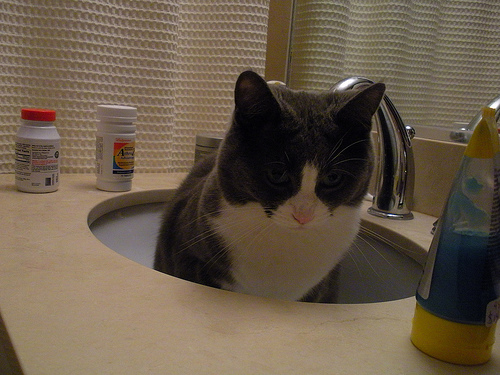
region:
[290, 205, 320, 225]
Nose of sitting cat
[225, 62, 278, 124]
Ear of sitting cat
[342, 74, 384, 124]
Ear of sitting cat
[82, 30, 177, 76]
Part of mini blinds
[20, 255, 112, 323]
Part of bathroom sink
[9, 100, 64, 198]
Supplement bottle on sink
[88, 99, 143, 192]
Supplement bottle on sink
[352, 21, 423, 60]
Part of mini blinds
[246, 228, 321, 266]
White chest of sitting cat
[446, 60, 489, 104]
Part of mini blinds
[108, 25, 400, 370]
a gray and white cat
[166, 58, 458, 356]
a gray and white cat in a sink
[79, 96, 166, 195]
a white pill bottle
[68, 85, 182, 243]
a white pill bottle on a sink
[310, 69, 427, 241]
a silver sink faucet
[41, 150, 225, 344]
a tan sink counter top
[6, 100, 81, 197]
a white bottle with red cap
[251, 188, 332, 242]
pink nose on a cat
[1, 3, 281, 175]
a white shower curtain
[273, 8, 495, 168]
a mirror on the wall in a bathroom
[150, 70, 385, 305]
Black and grey cat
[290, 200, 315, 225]
Pink nose on cat's face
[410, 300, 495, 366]
Yellow lid on container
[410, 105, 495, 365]
Yellow and blue tube on counter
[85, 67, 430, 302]
Cat sitting in bathroom sink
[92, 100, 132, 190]
White container sitting on counter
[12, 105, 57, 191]
White container with red lid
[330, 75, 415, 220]
Chrome faucet near bathroom sink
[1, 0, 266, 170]
White patterned wall in bathroom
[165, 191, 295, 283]
Whiskers on cat's face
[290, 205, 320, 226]
Nose of seated cat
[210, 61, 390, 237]
Head of seated cat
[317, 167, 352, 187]
Eye of seated cat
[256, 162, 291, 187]
Eye of seated cat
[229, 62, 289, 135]
Ear of seated cat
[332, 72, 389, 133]
Ear of seated cat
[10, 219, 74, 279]
Part of bathroom sink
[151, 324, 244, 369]
Part of bathroom sink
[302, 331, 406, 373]
Part of bathroom sink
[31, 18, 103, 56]
Part of white mini blinds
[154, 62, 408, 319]
a cat is in the sink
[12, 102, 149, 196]
some medicine is on the counter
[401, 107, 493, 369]
a bottle of lotion is on the counter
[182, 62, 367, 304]
the cat is grey and white in color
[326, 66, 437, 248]
the fixtures are silver in color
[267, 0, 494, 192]
a mirror is on the wall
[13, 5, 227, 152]
a white curtain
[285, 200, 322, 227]
the cats nose is pink in color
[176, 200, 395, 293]
the cat has whiskers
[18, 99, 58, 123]
the cap to this bottle is red